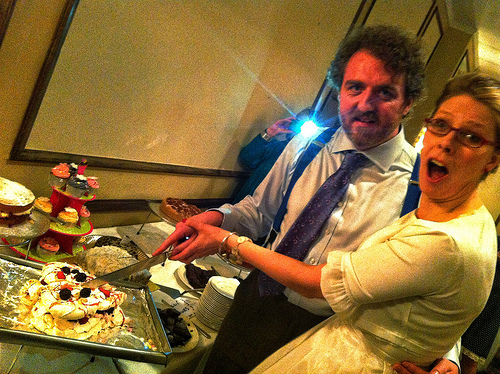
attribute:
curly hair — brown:
[360, 32, 432, 87]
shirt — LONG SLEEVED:
[208, 122, 418, 317]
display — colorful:
[39, 161, 101, 258]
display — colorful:
[132, 190, 202, 264]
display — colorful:
[1, 174, 51, 264]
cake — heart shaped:
[26, 259, 126, 338]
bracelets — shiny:
[195, 221, 242, 268]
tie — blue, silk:
[244, 149, 372, 306]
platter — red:
[27, 150, 102, 263]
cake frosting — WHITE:
[25, 257, 139, 348]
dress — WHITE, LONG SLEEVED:
[248, 202, 497, 370]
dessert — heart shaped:
[26, 259, 126, 340]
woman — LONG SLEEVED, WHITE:
[276, 49, 497, 371]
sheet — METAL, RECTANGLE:
[3, 248, 174, 360]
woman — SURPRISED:
[385, 63, 498, 305]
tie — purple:
[274, 141, 370, 256]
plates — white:
[193, 273, 240, 332]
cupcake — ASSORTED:
[44, 161, 70, 188]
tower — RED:
[4, 155, 103, 270]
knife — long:
[81, 249, 177, 286]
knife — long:
[159, 297, 211, 339]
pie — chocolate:
[160, 195, 202, 222]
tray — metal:
[147, 200, 177, 227]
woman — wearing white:
[169, 72, 496, 371]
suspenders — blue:
[245, 106, 342, 268]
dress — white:
[319, 205, 496, 372]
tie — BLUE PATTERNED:
[334, 135, 379, 227]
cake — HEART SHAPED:
[28, 260, 173, 346]